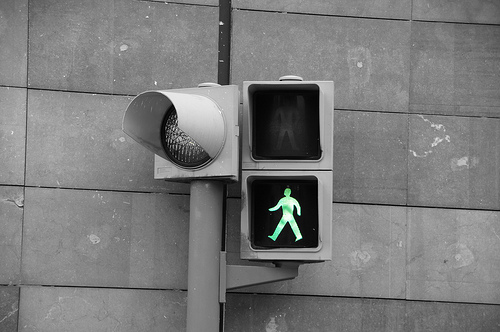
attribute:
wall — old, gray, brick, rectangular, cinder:
[0, 1, 500, 332]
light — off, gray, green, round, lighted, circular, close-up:
[122, 84, 242, 179]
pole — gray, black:
[185, 180, 224, 331]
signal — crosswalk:
[242, 81, 333, 261]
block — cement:
[2, 0, 28, 87]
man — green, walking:
[271, 97, 302, 152]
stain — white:
[403, 113, 454, 160]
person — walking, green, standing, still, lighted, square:
[266, 188, 306, 241]